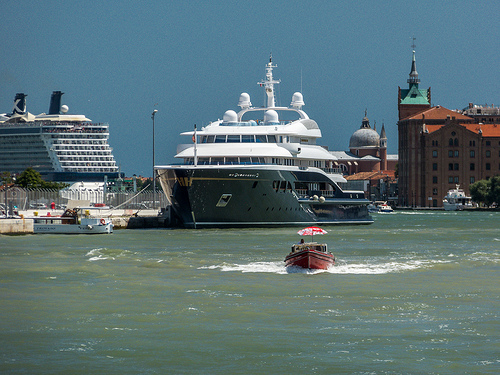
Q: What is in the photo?
A: Cruise ship.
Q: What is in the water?
A: Boat.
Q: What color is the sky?
A: Blue.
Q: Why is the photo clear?
A: Its during the day.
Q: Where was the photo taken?
A: In the ocean.